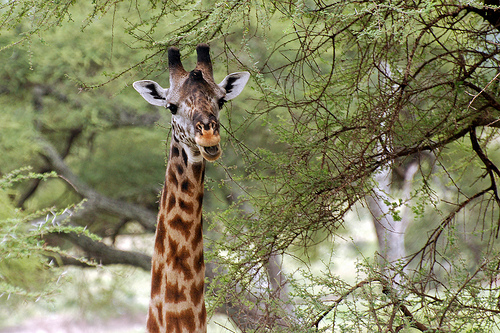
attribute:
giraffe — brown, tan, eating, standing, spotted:
[158, 44, 261, 331]